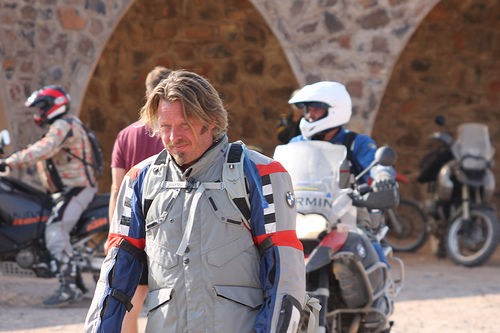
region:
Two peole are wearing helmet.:
[25, 55, 355, 148]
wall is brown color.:
[52, 30, 353, 85]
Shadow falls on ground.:
[390, 235, 470, 322]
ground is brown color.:
[315, 217, 470, 319]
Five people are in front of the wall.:
[7, 75, 362, 215]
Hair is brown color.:
[165, 77, 205, 107]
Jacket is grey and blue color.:
[102, 190, 262, 305]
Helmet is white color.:
[295, 82, 350, 129]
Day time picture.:
[11, 20, 466, 321]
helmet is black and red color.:
[23, 78, 71, 127]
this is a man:
[131, 83, 293, 308]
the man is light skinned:
[182, 131, 203, 143]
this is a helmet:
[286, 77, 348, 122]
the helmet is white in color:
[312, 84, 340, 100]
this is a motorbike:
[413, 128, 496, 216]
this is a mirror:
[426, 114, 446, 124]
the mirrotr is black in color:
[376, 149, 391, 157]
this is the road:
[410, 273, 499, 318]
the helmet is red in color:
[33, 92, 67, 110]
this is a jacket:
[157, 206, 249, 320]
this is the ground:
[418, 280, 474, 325]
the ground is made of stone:
[417, 287, 479, 328]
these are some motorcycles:
[11, 168, 488, 278]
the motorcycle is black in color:
[4, 191, 24, 205]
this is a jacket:
[108, 188, 295, 325]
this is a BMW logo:
[281, 190, 296, 217]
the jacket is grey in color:
[175, 282, 212, 322]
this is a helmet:
[285, 85, 361, 135]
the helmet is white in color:
[334, 100, 351, 119]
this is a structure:
[290, 13, 492, 70]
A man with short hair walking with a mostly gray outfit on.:
[81, 67, 309, 332]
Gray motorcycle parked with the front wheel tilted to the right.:
[415, 114, 498, 263]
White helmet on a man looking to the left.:
[285, 81, 353, 140]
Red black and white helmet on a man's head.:
[19, 85, 72, 127]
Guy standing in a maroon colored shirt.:
[104, 65, 175, 252]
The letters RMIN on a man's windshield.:
[294, 195, 334, 210]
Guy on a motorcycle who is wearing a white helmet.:
[264, 78, 399, 332]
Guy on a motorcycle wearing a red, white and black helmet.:
[1, 82, 100, 307]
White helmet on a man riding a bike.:
[285, 79, 350, 136]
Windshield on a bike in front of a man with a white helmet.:
[270, 142, 345, 221]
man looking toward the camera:
[58, 56, 318, 331]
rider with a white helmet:
[248, 67, 407, 329]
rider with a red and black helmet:
[5, 72, 110, 316]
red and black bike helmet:
[18, 74, 76, 126]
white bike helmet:
[286, 70, 359, 145]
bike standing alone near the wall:
[368, 96, 498, 276]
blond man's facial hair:
[162, 136, 195, 170]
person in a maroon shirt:
[94, 60, 186, 332]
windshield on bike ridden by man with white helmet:
[271, 133, 348, 231]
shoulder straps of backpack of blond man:
[138, 137, 258, 239]